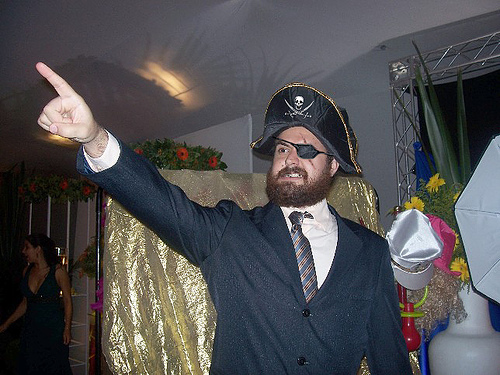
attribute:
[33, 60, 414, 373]
person — pointing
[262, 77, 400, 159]
hat — pirate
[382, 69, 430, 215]
stand — Metal 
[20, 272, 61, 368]
dress — blue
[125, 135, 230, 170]
decoration — floral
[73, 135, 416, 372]
jacket — blue